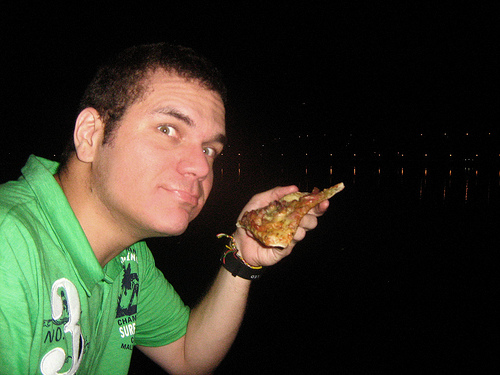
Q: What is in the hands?
A: Pizza.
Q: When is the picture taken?
A: Night time.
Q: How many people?
A: 1.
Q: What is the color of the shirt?
A: Green.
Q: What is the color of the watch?
A: Black.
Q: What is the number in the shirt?
A: 3.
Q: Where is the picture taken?
A: At a waterside.